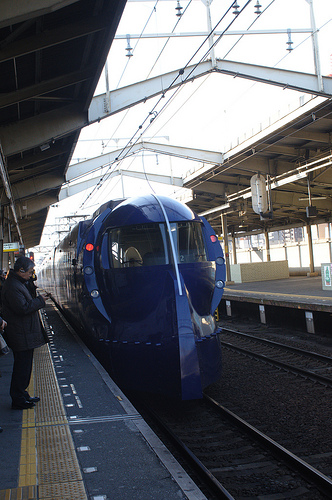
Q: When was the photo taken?
A: Daytime.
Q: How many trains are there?
A: One.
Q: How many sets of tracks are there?
A: Two.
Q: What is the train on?
A: Tracks.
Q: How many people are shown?
A: One.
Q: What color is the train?
A: Blue.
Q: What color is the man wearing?
A: Black.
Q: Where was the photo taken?
A: A train station.